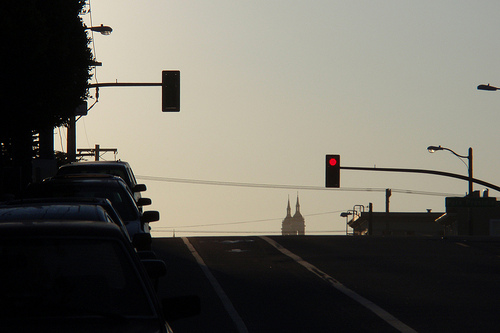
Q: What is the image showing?
A: It is showing a street.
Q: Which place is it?
A: It is a street.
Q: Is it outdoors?
A: Yes, it is outdoors.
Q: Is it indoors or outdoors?
A: It is outdoors.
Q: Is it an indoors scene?
A: No, it is outdoors.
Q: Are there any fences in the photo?
A: No, there are no fences.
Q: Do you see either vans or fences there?
A: No, there are no fences or vans.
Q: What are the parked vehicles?
A: The vehicles are cars.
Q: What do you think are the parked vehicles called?
A: The vehicles are cars.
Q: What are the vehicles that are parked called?
A: The vehicles are cars.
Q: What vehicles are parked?
A: The vehicles are cars.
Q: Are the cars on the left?
A: Yes, the cars are on the left of the image.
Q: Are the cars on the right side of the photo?
A: No, the cars are on the left of the image.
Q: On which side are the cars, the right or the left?
A: The cars are on the left of the image.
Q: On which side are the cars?
A: The cars are on the left of the image.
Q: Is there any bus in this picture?
A: No, there are no buses.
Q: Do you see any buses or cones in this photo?
A: No, there are no buses or cones.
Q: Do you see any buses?
A: No, there are no buses.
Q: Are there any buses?
A: No, there are no buses.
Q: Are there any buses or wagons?
A: No, there are no buses or wagons.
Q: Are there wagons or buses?
A: No, there are no buses or wagons.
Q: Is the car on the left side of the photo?
A: Yes, the car is on the left of the image.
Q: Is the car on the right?
A: No, the car is on the left of the image.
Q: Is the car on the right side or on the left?
A: The car is on the left of the image.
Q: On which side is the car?
A: The car is on the left of the image.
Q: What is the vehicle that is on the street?
A: The vehicle is a car.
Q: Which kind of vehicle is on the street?
A: The vehicle is a car.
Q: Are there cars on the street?
A: Yes, there is a car on the street.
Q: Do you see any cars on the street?
A: Yes, there is a car on the street.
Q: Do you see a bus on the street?
A: No, there is a car on the street.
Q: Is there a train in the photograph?
A: No, there are no trains.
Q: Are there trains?
A: No, there are no trains.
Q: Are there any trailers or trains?
A: No, there are no trains or trailers.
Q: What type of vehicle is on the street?
A: The vehicle is a car.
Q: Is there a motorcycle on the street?
A: No, there is a car on the street.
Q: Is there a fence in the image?
A: No, there are no fences.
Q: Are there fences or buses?
A: No, there are no fences or buses.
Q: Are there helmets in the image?
A: No, there are no helmets.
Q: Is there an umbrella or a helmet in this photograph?
A: No, there are no helmets or umbrellas.